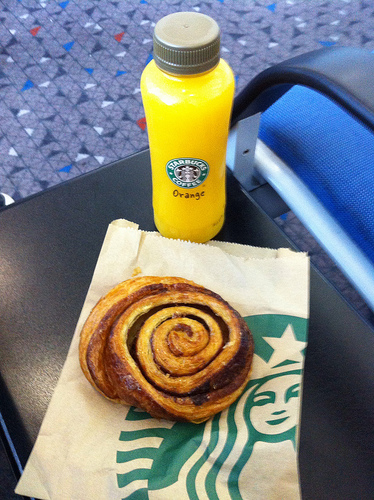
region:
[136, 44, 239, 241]
the bottle is yellow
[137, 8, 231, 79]
the bottle cap is gray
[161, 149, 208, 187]
green logo on bottle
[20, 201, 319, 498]
the wrapper is white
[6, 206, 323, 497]
green logo on wrapper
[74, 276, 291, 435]
cinnamon roll on the wrapper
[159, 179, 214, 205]
black letters on bottle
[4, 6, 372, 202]
the carpet is gray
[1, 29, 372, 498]
food laying on a chair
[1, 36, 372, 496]
the chair is black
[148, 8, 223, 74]
grey cap to yellow bottle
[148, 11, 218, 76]
grey cap on bottle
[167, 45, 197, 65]
ridges on side of cap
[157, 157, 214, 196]
logo on front of bottle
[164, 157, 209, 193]
starbucks logo on bottle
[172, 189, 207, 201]
black writing on bottle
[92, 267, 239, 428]
brown and tan food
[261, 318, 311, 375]
small star on top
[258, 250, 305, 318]
brown paper wrapper for food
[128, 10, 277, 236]
this is a bottle of orange juice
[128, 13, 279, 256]
a juice bottle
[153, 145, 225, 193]
this is the starbucks logo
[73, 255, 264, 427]
a large cinnamon roll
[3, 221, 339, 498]
a pastry bag from starbucks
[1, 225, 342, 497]
a paper bag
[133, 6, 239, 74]
the cap is grey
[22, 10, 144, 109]
this is a patterned carpet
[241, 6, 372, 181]
the arm rest of a chair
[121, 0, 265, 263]
the bottle is closed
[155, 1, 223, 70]
grey cap to bottle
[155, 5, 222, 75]
grey cap to yellow bottle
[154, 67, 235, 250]
yellow bottle of liquid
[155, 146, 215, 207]
green logo on bottle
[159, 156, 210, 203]
green starbucks logo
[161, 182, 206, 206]
black writing on bottle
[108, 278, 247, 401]
brown and tan food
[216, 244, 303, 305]
brown paper bag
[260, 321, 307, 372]
white star on top of logo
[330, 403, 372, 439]
Small part of the black seat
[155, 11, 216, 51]
Gray lid of the bottle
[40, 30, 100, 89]
Small patch of the ground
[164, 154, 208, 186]
Starbucks logo on bottle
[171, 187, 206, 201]
Orange indicated on bottle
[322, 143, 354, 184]
Blue part of the chair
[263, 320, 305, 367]
Star on Starbucks napkin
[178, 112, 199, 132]
Yellow part on the bottle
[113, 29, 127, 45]
Red triangle on the ground